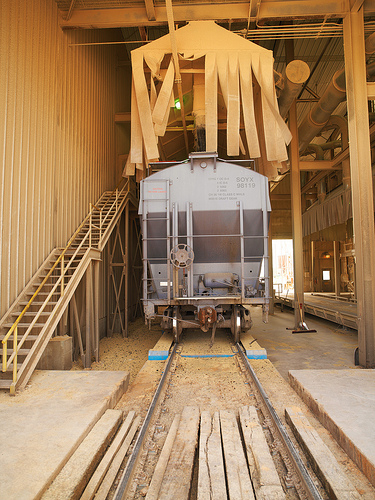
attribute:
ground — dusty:
[0, 364, 124, 489]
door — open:
[271, 239, 294, 303]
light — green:
[174, 97, 182, 110]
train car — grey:
[138, 153, 270, 343]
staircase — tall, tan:
[4, 183, 128, 390]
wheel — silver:
[226, 304, 243, 342]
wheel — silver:
[166, 304, 184, 341]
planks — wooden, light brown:
[136, 402, 283, 497]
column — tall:
[284, 102, 311, 324]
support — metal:
[339, 8, 373, 367]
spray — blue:
[142, 344, 269, 363]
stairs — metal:
[4, 173, 133, 404]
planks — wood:
[144, 399, 291, 499]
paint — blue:
[144, 345, 267, 366]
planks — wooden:
[142, 339, 272, 366]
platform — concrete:
[27, 375, 97, 430]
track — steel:
[245, 325, 284, 407]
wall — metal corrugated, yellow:
[6, 43, 93, 209]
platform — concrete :
[3, 366, 132, 495]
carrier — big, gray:
[134, 146, 273, 338]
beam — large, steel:
[284, 102, 309, 328]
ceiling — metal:
[73, 11, 352, 74]